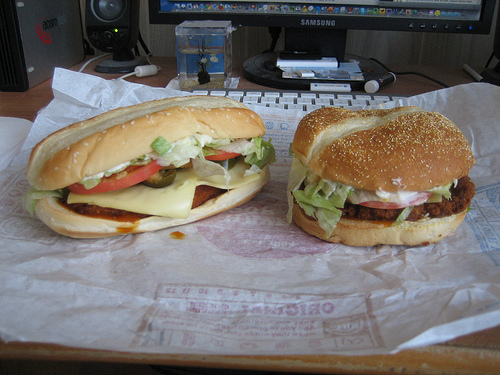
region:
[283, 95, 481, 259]
a hamburger on the table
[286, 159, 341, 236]
lettuce on the hamburger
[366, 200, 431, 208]
a tomato on the hamburger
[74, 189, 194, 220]
a cheese on a hamburger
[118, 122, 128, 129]
a sesame seed on a bun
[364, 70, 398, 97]
a lip balm on the desk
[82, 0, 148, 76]
a partially seen speaker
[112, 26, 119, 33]
an off and on light of the speaker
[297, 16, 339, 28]
a SAMSUNG print on the monitor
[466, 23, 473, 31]
an off and on light of a monitor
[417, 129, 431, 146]
part of a bread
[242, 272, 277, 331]
part of a cloth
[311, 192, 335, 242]
part of a cabbage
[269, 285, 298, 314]
part of a poster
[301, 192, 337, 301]
part of a cabbage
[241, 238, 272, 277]
part of a paper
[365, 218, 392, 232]
edge of a burn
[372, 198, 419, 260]
part of a mear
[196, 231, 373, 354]
the paper is white in colour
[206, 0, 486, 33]
the television is on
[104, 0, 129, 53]
the light is on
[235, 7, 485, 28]
the tv is black in colour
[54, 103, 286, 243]
the sandwich is brown in colour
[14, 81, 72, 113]
the table is brown in colour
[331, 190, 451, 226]
the sandwich is brown in colour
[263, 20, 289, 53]
the plug is black in colour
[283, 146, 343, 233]
the veggetable is green in colour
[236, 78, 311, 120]
the keyboard is white in colour